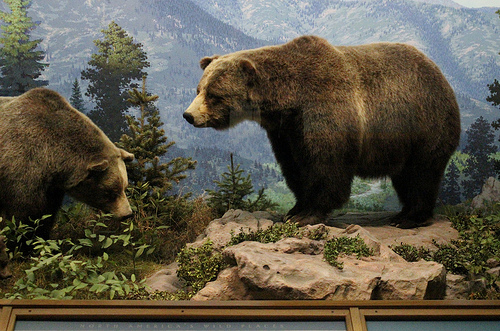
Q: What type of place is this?
A: It is a field.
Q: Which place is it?
A: It is a field.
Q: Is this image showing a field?
A: Yes, it is showing a field.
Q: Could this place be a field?
A: Yes, it is a field.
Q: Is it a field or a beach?
A: It is a field.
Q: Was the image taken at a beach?
A: No, the picture was taken in a field.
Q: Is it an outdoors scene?
A: Yes, it is outdoors.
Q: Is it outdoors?
A: Yes, it is outdoors.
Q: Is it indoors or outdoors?
A: It is outdoors.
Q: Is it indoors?
A: No, it is outdoors.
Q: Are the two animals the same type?
A: Yes, all the animals are bears.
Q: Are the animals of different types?
A: No, all the animals are bears.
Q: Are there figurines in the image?
A: No, there are no figurines.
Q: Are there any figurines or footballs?
A: No, there are no figurines or footballs.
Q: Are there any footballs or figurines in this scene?
A: No, there are no figurines or footballs.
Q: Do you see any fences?
A: No, there are no fences.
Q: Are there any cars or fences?
A: No, there are no fences or cars.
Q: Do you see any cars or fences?
A: No, there are no fences or cars.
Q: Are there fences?
A: No, there are no fences.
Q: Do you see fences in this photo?
A: No, there are no fences.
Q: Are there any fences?
A: No, there are no fences.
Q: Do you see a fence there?
A: No, there are no fences.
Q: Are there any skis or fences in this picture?
A: No, there are no fences or skis.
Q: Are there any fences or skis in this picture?
A: No, there are no fences or skis.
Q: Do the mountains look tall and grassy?
A: Yes, the mountains are tall and grassy.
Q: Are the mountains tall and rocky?
A: No, the mountains are tall but grassy.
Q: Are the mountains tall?
A: Yes, the mountains are tall.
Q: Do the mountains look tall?
A: Yes, the mountains are tall.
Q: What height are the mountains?
A: The mountains are tall.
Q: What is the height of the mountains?
A: The mountains are tall.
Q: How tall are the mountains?
A: The mountains are tall.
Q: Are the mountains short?
A: No, the mountains are tall.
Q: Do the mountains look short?
A: No, the mountains are tall.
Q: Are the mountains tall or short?
A: The mountains are tall.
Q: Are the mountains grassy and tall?
A: Yes, the mountains are grassy and tall.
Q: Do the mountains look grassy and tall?
A: Yes, the mountains are grassy and tall.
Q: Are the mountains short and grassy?
A: No, the mountains are grassy but tall.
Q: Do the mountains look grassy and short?
A: No, the mountains are grassy but tall.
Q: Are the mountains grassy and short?
A: No, the mountains are grassy but tall.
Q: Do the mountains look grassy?
A: Yes, the mountains are grassy.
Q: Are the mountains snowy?
A: No, the mountains are grassy.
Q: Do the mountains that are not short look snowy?
A: No, the mountains are grassy.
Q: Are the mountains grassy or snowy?
A: The mountains are grassy.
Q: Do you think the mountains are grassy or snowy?
A: The mountains are grassy.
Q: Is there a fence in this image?
A: No, there are no fences.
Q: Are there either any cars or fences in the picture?
A: No, there are no fences or cars.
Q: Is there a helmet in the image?
A: No, there are no helmets.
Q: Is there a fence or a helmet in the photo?
A: No, there are no helmets or fences.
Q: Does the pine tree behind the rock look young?
A: Yes, the pine is young.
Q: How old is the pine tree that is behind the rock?
A: The pine tree is young.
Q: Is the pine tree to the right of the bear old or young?
A: The pine is young.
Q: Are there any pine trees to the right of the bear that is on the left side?
A: Yes, there is a pine tree to the right of the bear.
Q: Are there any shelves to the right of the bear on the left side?
A: No, there is a pine tree to the right of the bear.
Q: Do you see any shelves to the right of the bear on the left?
A: No, there is a pine tree to the right of the bear.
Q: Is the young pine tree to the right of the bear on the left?
A: Yes, the pine is to the right of the bear.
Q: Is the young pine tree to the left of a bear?
A: Yes, the pine is to the left of a bear.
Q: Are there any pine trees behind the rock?
A: Yes, there is a pine tree behind the rock.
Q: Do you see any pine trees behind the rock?
A: Yes, there is a pine tree behind the rock.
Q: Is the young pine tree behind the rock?
A: Yes, the pine is behind the rock.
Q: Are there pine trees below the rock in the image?
A: Yes, there is a pine tree below the rock.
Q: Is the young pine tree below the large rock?
A: Yes, the pine is below the rock.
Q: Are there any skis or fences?
A: No, there are no fences or skis.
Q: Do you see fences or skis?
A: No, there are no fences or skis.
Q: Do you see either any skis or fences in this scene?
A: No, there are no fences or skis.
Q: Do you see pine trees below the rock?
A: Yes, there is a pine tree below the rock.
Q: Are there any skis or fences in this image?
A: No, there are no fences or skis.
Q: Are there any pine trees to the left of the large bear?
A: Yes, there is a pine tree to the left of the bear.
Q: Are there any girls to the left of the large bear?
A: No, there is a pine tree to the left of the bear.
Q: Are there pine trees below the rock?
A: Yes, there is a pine tree below the rock.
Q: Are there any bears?
A: Yes, there is a bear.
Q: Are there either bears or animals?
A: Yes, there is a bear.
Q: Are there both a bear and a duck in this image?
A: No, there is a bear but no ducks.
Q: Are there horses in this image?
A: No, there are no horses.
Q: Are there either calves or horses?
A: No, there are no horses or calves.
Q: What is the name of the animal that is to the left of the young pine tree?
A: The animal is a bear.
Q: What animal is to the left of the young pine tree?
A: The animal is a bear.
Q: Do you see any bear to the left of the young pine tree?
A: Yes, there is a bear to the left of the pine tree.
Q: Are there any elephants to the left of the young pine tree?
A: No, there is a bear to the left of the pine tree.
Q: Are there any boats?
A: No, there are no boats.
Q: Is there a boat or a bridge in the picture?
A: No, there are no boats or bridges.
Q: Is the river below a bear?
A: Yes, the river is below a bear.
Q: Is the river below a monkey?
A: No, the river is below a bear.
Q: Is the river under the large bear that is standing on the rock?
A: Yes, the river is under the bear.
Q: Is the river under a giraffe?
A: No, the river is under the bear.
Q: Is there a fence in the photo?
A: No, there are no fences.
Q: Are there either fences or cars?
A: No, there are no fences or cars.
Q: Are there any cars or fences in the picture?
A: No, there are no fences or cars.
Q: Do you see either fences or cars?
A: No, there are no fences or cars.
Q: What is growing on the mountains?
A: The trees are growing on the mountains.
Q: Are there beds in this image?
A: No, there are no beds.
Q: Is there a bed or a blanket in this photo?
A: No, there are no beds or blankets.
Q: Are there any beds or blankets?
A: No, there are no beds or blankets.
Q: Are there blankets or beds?
A: No, there are no beds or blankets.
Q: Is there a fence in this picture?
A: No, there are no fences.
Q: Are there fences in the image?
A: No, there are no fences.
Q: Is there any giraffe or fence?
A: No, there are no fences or giraffes.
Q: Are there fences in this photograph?
A: No, there are no fences.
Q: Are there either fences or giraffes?
A: No, there are no fences or giraffes.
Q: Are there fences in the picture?
A: No, there are no fences.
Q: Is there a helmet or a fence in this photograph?
A: No, there are no fences or helmets.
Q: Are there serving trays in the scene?
A: No, there are no serving trays.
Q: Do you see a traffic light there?
A: No, there are no traffic lights.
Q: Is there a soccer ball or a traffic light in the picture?
A: No, there are no traffic lights or soccer balls.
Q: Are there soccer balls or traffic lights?
A: No, there are no traffic lights or soccer balls.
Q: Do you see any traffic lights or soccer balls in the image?
A: No, there are no traffic lights or soccer balls.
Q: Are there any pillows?
A: No, there are no pillows.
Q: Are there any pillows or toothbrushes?
A: No, there are no pillows or toothbrushes.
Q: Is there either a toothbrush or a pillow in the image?
A: No, there are no pillows or toothbrushes.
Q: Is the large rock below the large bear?
A: Yes, the rock is below the bear.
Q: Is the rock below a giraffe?
A: No, the rock is below the bear.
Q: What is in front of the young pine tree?
A: The rock is in front of the pine.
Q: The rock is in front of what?
A: The rock is in front of the pine tree.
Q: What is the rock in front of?
A: The rock is in front of the pine tree.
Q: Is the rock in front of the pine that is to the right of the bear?
A: Yes, the rock is in front of the pine.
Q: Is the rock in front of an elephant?
A: No, the rock is in front of the pine.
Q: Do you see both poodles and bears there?
A: No, there is a bear but no poodles.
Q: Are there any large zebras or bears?
A: Yes, there is a large bear.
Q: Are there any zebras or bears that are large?
A: Yes, the bear is large.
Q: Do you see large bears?
A: Yes, there is a large bear.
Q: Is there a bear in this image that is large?
A: Yes, there is a bear that is large.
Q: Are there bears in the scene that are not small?
A: Yes, there is a large bear.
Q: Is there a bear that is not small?
A: Yes, there is a large bear.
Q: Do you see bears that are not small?
A: Yes, there is a large bear.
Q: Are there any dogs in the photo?
A: No, there are no dogs.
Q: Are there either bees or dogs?
A: No, there are no dogs or bees.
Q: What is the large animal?
A: The animal is a bear.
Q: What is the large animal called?
A: The animal is a bear.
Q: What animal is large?
A: The animal is a bear.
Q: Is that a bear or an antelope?
A: That is a bear.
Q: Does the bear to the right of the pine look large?
A: Yes, the bear is large.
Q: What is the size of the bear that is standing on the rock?
A: The bear is large.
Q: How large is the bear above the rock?
A: The bear is large.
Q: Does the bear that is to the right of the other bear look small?
A: No, the bear is large.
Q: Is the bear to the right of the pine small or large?
A: The bear is large.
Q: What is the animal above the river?
A: The animal is a bear.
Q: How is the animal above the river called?
A: The animal is a bear.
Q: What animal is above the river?
A: The animal is a bear.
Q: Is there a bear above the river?
A: Yes, there is a bear above the river.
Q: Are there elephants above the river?
A: No, there is a bear above the river.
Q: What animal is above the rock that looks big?
A: The animal is a bear.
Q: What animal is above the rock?
A: The animal is a bear.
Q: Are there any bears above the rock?
A: Yes, there is a bear above the rock.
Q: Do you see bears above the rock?
A: Yes, there is a bear above the rock.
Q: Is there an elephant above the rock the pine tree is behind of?
A: No, there is a bear above the rock.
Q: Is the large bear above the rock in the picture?
A: Yes, the bear is above the rock.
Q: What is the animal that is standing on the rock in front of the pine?
A: The animal is a bear.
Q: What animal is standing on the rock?
A: The animal is a bear.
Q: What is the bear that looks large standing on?
A: The bear is standing on the rock.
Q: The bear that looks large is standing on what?
A: The bear is standing on the rock.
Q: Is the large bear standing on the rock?
A: Yes, the bear is standing on the rock.